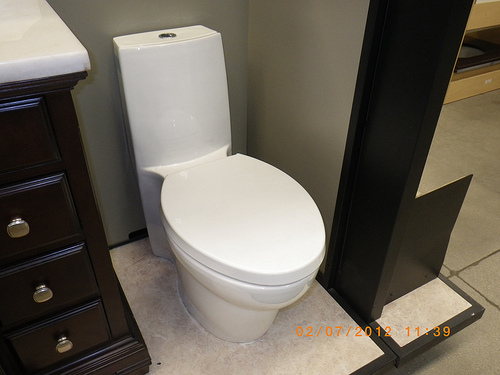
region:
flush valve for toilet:
[156, 29, 181, 38]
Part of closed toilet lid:
[155, 171, 331, 288]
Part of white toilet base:
[167, 250, 322, 338]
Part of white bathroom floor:
[296, 326, 343, 370]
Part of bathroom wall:
[257, 29, 317, 88]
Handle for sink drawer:
[3, 215, 26, 241]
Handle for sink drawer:
[29, 276, 54, 302]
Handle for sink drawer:
[51, 330, 76, 357]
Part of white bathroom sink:
[20, 42, 70, 62]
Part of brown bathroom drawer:
[8, 122, 57, 154]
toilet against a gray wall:
[110, 23, 329, 349]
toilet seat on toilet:
[148, 148, 334, 289]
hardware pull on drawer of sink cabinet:
[5, 217, 31, 240]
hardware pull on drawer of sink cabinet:
[27, 281, 54, 306]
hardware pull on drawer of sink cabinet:
[52, 334, 74, 354]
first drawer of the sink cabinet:
[2, 170, 87, 249]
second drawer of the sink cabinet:
[2, 239, 102, 325]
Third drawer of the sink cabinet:
[2, 298, 114, 370]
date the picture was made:
[291, 323, 393, 345]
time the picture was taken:
[403, 323, 453, 345]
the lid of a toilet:
[155, 151, 329, 286]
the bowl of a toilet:
[161, 234, 326, 313]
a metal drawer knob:
[3, 215, 35, 242]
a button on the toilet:
[156, 25, 178, 42]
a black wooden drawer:
[0, 170, 92, 270]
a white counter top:
[0, 1, 97, 86]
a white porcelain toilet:
[106, 20, 333, 348]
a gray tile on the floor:
[456, 245, 499, 310]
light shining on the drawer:
[0, 92, 47, 115]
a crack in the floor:
[453, 246, 498, 278]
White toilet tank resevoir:
[107, 20, 256, 144]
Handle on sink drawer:
[28, 283, 56, 303]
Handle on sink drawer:
[47, 331, 81, 357]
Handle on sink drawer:
[2, 210, 33, 245]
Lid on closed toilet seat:
[157, 151, 339, 286]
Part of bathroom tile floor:
[293, 335, 335, 365]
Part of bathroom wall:
[279, 37, 326, 85]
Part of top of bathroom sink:
[7, 28, 52, 65]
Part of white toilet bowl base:
[168, 245, 321, 348]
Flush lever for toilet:
[156, 29, 180, 41]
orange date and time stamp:
[291, 321, 461, 345]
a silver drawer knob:
[0, 215, 35, 242]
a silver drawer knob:
[34, 279, 51, 307]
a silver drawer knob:
[53, 331, 75, 356]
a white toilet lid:
[151, 146, 328, 284]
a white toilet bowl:
[154, 228, 310, 352]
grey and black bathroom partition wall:
[279, 56, 414, 173]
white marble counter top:
[12, 21, 80, 83]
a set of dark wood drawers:
[9, 151, 111, 373]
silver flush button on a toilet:
[159, 27, 178, 42]